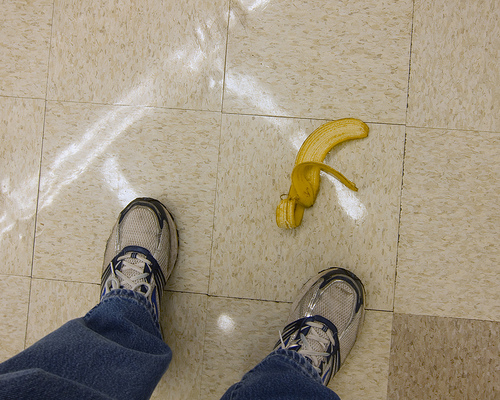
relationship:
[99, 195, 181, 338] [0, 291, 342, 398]
left shoe on person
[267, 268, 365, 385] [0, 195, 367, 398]
shoe of person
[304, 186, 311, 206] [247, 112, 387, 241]
mark on banana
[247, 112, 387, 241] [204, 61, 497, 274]
banana on ground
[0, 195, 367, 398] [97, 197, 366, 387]
person wearing shoes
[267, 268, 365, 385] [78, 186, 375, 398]
shoe on person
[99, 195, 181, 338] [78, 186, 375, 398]
left shoe on person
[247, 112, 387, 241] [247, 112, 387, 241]
banana on banana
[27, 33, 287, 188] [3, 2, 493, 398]
sunlit on tiles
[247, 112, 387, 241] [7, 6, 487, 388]
banana on floor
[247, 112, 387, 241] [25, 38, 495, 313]
banana on ground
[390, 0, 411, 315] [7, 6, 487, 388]
lines on floor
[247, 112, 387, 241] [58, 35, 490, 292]
banana on floor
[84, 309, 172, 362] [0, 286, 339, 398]
wrinkle in jeans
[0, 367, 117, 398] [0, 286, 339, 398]
wrinkle in jeans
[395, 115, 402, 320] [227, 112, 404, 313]
edge between floor tiles